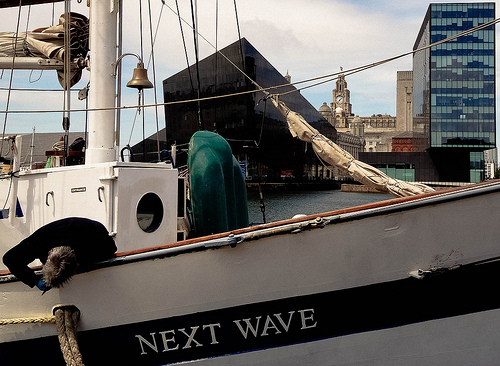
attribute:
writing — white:
[133, 293, 324, 359]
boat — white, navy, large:
[3, 0, 500, 357]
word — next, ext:
[134, 317, 224, 358]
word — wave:
[232, 307, 325, 339]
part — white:
[5, 3, 499, 357]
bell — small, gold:
[110, 47, 152, 101]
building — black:
[314, 65, 358, 137]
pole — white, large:
[88, 0, 125, 167]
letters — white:
[131, 319, 228, 355]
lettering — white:
[232, 301, 315, 344]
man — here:
[2, 214, 118, 296]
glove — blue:
[37, 280, 50, 291]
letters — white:
[134, 297, 327, 357]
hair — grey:
[39, 241, 78, 290]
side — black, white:
[2, 185, 499, 359]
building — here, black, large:
[161, 35, 339, 149]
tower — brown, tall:
[332, 63, 355, 129]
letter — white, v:
[274, 305, 298, 336]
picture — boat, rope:
[5, 6, 497, 357]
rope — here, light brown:
[3, 21, 498, 130]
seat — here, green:
[183, 130, 253, 237]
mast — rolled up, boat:
[284, 104, 434, 204]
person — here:
[3, 216, 116, 289]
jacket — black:
[2, 216, 123, 287]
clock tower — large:
[329, 66, 351, 125]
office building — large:
[164, 34, 340, 158]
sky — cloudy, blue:
[9, 0, 427, 149]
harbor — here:
[11, 0, 429, 162]